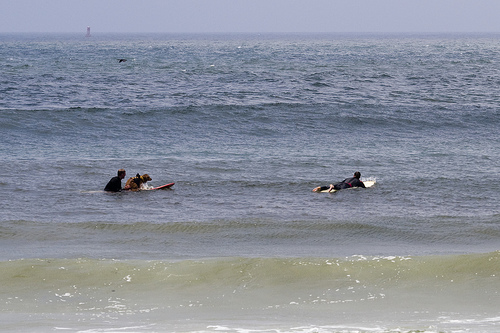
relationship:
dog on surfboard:
[123, 172, 152, 191] [137, 179, 175, 192]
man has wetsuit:
[310, 169, 368, 193] [320, 178, 370, 190]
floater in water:
[84, 25, 92, 37] [0, 32, 499, 330]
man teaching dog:
[102, 169, 127, 192] [123, 172, 152, 191]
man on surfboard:
[310, 169, 368, 193] [321, 178, 376, 194]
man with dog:
[102, 169, 127, 192] [123, 172, 152, 191]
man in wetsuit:
[310, 169, 368, 193] [320, 178, 370, 190]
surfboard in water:
[137, 179, 175, 192] [0, 32, 499, 330]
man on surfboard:
[102, 169, 127, 192] [137, 179, 175, 192]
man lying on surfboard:
[310, 169, 368, 193] [321, 178, 376, 194]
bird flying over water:
[111, 56, 129, 66] [0, 32, 499, 330]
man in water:
[310, 169, 368, 193] [0, 32, 499, 330]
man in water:
[102, 169, 127, 192] [0, 32, 499, 330]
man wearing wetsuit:
[310, 169, 368, 193] [320, 178, 370, 190]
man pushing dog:
[102, 169, 127, 192] [123, 172, 152, 191]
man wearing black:
[102, 169, 127, 192] [104, 175, 123, 194]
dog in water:
[123, 172, 152, 191] [0, 32, 499, 330]